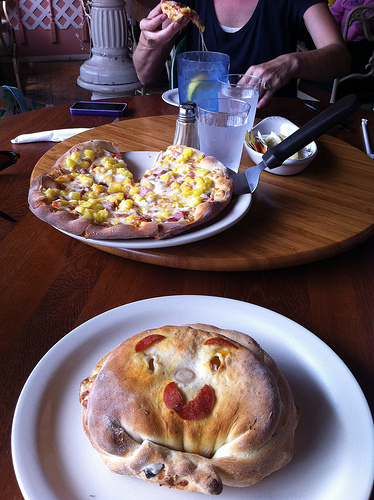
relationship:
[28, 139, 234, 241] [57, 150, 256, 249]
pizza on top of plate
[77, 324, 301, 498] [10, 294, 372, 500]
foldover on top of plate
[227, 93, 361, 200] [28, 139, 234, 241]
spatula under pizza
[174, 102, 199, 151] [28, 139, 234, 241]
pepper behind pizza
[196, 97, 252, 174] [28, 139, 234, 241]
glass behind pizza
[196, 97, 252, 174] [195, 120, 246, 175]
glass with water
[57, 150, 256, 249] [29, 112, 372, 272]
plate on top of platter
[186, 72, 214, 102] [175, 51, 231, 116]
lemon inside of glass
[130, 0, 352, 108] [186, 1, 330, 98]
person wearing shirt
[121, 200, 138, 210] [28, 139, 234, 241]
pineapple on top of pizza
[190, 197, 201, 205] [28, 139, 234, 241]
pinapple on top of pizza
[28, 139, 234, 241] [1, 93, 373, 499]
pizza on top of table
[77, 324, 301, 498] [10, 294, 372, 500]
pastry on top of plate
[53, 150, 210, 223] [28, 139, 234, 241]
toppings on top of pizza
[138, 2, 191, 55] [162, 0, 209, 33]
hand holding pizza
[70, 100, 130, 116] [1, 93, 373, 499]
cellphone on top of table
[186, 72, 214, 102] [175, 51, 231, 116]
lemon inside of tumbler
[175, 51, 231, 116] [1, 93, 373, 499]
glass on top of table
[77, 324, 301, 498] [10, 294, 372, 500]
calzone on top of plate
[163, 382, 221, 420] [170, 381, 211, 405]
pepperoni shaped mouth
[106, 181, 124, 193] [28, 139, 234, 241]
pineapple on top of pizza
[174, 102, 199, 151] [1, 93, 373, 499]
shaker on top of table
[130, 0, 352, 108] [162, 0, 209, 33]
person holding pizza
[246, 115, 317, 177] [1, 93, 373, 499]
bowl on top of table